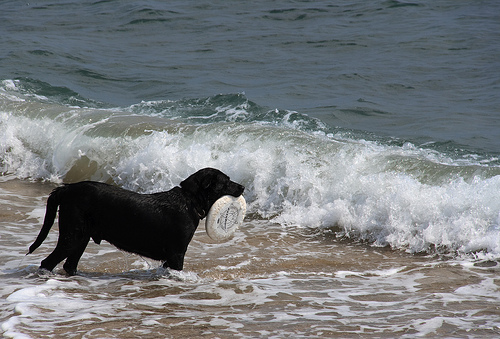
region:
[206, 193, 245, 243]
A frisbee in the dog's mouth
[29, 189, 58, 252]
The tail of the dog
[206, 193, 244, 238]
The frisbee is circular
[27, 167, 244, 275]
A dog standing in the water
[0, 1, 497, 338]
Water beneath the dog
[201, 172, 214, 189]
The right ear of the dog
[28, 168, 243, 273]
The dog has black fur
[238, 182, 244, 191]
The nose of the dog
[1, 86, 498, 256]
A small wave in the water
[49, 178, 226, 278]
dog on the ocean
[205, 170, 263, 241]
dog is carrying firsbee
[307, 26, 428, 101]
the body of water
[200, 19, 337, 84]
the water is calm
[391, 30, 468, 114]
the water is green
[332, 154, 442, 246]
the waves are crashing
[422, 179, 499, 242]
the waves are white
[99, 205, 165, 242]
the dog is black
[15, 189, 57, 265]
tail of the dog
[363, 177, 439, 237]
the water is white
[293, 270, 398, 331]
bubbles in the water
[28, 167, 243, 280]
a black dog in the water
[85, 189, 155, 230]
the dogs fur is black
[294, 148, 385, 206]
a small wave in the water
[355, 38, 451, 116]
the water is blue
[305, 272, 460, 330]
bubbles in the water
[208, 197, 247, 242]
a white frisbee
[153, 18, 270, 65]
the ocean water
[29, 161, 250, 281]
this is a dog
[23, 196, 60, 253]
this is the tail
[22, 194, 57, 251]
the tail is long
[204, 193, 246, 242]
this is a frisbee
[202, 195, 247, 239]
the frisbee is white in color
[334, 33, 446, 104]
the water is green in color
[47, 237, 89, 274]
these are the legs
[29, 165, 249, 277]
A dark dog in the sea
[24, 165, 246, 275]
A dark dog playing catch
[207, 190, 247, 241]
A white rounded frisbee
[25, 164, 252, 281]
A dog with a frisbee in mouth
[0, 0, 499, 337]
The open cold sea water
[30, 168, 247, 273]
A chubby dog catching a frisbee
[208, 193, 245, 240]
The white frisbee with a dark line mark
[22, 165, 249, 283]
A canine inside the water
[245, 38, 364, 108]
Large body of water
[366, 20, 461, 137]
Large body of water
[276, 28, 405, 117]
Large body of water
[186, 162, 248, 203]
Head of a dog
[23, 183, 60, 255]
Tail of a dog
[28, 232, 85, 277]
Legs of a dog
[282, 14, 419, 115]
Large body of water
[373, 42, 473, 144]
Large body of water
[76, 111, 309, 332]
a dog in the water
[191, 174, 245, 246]
a dog holding a fribsee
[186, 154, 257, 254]
a dog holding a white frisbee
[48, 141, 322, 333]
a dog is black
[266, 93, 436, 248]
a wave on the water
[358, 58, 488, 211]
a body of murky water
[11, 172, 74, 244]
a tail on the dog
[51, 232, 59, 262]
a leg on the dog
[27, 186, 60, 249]
tail of a dog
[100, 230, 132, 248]
stomach of a dog